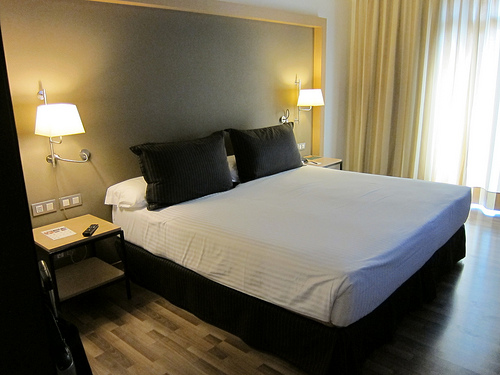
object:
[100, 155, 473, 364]
bed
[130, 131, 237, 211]
pillow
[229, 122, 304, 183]
pillow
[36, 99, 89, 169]
lamp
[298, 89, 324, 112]
lamp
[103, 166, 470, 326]
bed cover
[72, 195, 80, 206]
switch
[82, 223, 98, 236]
remote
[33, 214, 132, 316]
table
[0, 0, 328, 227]
wall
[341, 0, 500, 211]
curtain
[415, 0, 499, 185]
window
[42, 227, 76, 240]
paper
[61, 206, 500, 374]
floor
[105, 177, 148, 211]
pillow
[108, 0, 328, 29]
frame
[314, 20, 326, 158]
frame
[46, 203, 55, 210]
socket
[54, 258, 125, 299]
rack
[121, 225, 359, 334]
bed skirt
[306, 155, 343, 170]
table